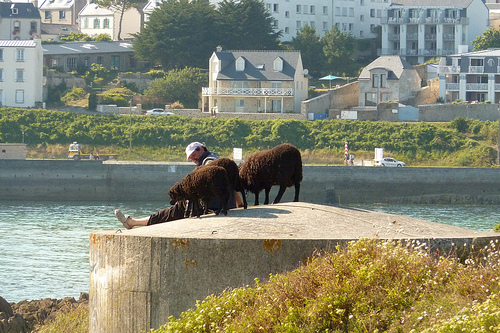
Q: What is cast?
A: Shadow.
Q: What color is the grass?
A: Green.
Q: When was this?
A: Daytime.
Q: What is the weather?
A: Sunny.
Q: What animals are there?
A: Sheep.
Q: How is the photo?
A: Clear.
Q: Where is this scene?
A: Close to river.